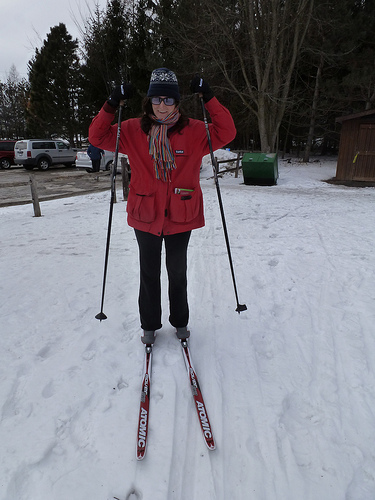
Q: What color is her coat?
A: Red.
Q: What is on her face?
A: Glasses.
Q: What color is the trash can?
A: Green.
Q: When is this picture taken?
A: Daytime.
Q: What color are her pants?
A: Black.